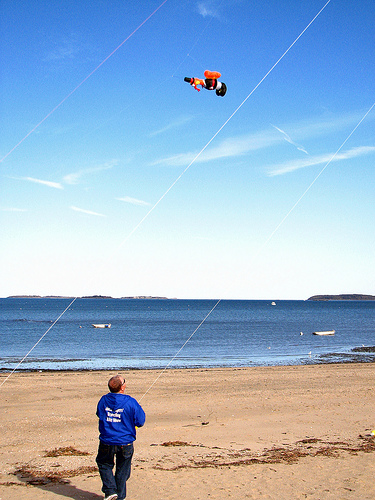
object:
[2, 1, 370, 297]
sky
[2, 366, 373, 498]
beach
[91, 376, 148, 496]
man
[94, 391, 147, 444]
shirt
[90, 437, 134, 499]
jeans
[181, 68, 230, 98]
kite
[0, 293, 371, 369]
water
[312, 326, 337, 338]
boat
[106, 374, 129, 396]
head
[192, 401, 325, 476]
sand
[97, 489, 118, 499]
shoes